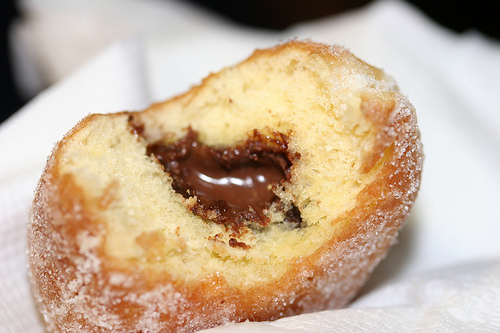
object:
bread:
[22, 33, 422, 333]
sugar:
[378, 119, 424, 242]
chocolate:
[140, 127, 294, 227]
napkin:
[0, 1, 499, 333]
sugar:
[25, 175, 239, 332]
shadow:
[348, 215, 418, 305]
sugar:
[148, 310, 271, 326]